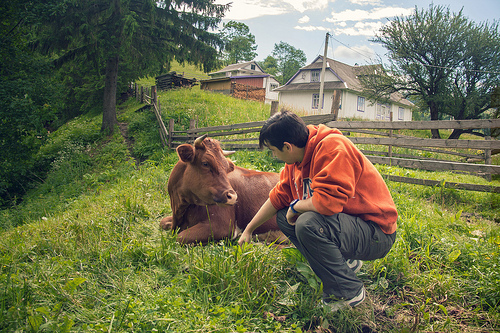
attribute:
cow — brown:
[157, 135, 292, 250]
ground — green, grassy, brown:
[8, 87, 499, 324]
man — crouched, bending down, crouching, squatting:
[233, 105, 401, 308]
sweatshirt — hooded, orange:
[260, 121, 403, 236]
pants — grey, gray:
[273, 202, 398, 303]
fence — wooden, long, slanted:
[124, 80, 499, 196]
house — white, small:
[275, 55, 418, 127]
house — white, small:
[205, 58, 280, 104]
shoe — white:
[317, 283, 368, 312]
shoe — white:
[339, 256, 366, 273]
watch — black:
[287, 196, 302, 216]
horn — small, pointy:
[194, 132, 211, 149]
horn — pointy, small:
[221, 151, 238, 158]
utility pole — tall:
[313, 30, 332, 118]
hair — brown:
[258, 108, 310, 149]